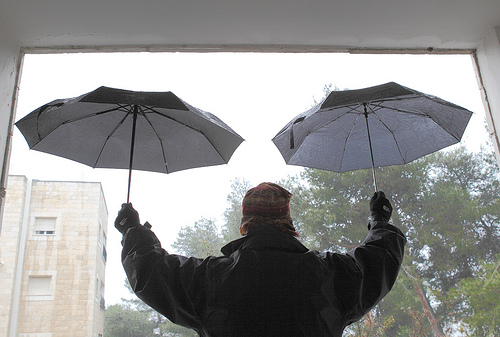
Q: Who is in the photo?
A: A man.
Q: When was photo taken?
A: Daytime.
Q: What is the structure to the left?
A: Buildings.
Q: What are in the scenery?
A: Trees.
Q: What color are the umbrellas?
A: Grey.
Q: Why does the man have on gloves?
A: Keep hands warm.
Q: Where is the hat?
A: On the man head.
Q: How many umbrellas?
A: Two.